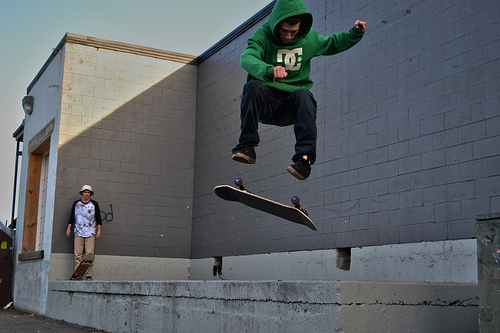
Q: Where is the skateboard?
A: In the air.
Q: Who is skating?
A: Man.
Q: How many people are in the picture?
A: Two.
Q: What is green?
A: Shirt.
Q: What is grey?
A: Ground.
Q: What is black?
A: Wheels.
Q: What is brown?
A: Building.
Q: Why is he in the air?
A: Skating.